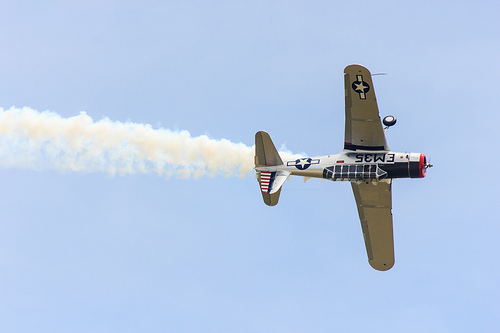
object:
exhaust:
[0, 109, 254, 177]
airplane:
[253, 63, 421, 265]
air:
[0, 0, 500, 333]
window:
[369, 167, 379, 173]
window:
[343, 165, 348, 172]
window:
[336, 165, 344, 174]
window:
[325, 169, 328, 177]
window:
[357, 173, 362, 178]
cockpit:
[383, 169, 387, 181]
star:
[294, 155, 321, 172]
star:
[351, 73, 369, 96]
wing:
[341, 64, 388, 150]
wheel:
[381, 115, 400, 130]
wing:
[349, 177, 397, 272]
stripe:
[263, 185, 269, 188]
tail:
[253, 130, 285, 207]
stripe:
[264, 178, 269, 181]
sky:
[0, 6, 500, 333]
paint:
[420, 155, 424, 170]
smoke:
[0, 118, 261, 175]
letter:
[390, 153, 398, 166]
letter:
[376, 155, 387, 161]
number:
[356, 152, 360, 164]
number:
[360, 153, 372, 168]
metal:
[337, 178, 343, 181]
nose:
[430, 163, 436, 170]